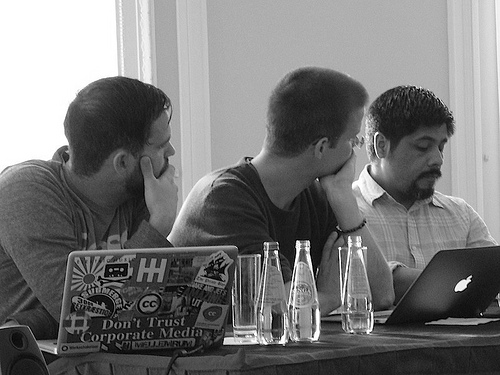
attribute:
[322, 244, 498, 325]
laptop — open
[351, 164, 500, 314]
shirt — plaid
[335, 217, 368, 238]
bracelet — black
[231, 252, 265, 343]
glass — clear, oblong, tall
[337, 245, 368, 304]
glass — clear, oblong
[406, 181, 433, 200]
beard — black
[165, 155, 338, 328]
shirt — black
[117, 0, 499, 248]
wall — white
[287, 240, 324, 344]
bottle — glass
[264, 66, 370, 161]
hair — short, dark